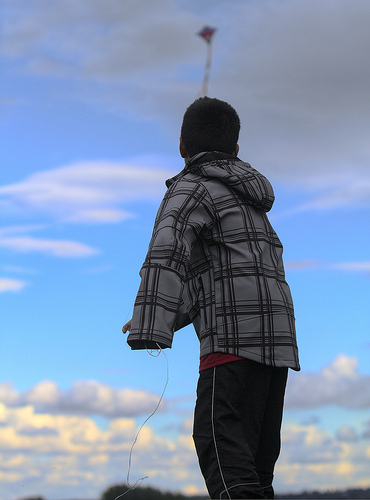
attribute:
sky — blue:
[0, 1, 368, 481]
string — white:
[127, 342, 170, 500]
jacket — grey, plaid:
[126, 151, 302, 372]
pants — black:
[192, 358, 289, 499]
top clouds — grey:
[2, 4, 367, 170]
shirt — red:
[192, 353, 249, 371]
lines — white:
[206, 368, 228, 500]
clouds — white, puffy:
[2, 160, 192, 491]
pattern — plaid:
[201, 192, 271, 345]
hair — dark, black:
[178, 97, 244, 161]